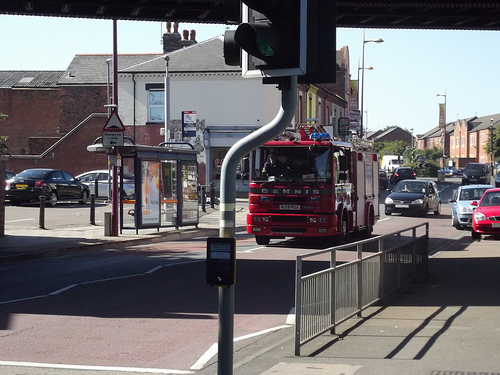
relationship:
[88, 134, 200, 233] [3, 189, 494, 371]
bus stop next to road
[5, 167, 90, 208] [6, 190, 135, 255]
car sitting in road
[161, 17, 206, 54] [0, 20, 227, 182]
chimneys on top of building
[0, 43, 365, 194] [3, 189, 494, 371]
assorted buildings across road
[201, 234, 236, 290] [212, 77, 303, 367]
box on pole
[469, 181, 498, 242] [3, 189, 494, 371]
car going down road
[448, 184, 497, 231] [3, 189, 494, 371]
car going down road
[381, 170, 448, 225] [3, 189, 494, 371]
car going down road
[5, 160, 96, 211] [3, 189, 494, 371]
car going down road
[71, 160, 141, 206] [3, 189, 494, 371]
car going down road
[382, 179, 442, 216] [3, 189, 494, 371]
car on road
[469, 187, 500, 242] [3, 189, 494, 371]
car on road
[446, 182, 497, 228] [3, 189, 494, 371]
car on road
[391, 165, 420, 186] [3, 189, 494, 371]
car on road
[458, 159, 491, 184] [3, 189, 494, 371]
car on road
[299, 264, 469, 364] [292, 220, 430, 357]
reflection of fence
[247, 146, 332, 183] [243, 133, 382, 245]
windshield of bus